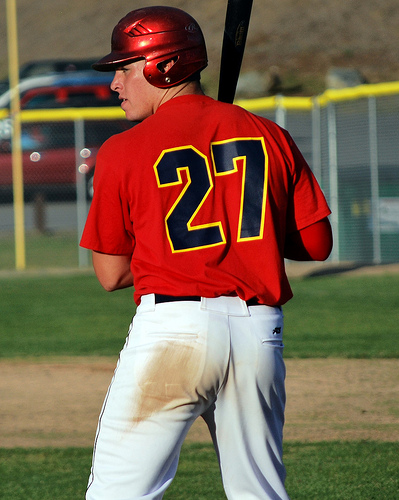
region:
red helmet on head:
[97, 6, 204, 89]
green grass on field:
[289, 444, 397, 498]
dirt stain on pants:
[127, 333, 212, 423]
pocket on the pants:
[149, 328, 204, 352]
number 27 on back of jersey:
[152, 136, 275, 249]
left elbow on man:
[95, 266, 126, 299]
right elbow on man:
[295, 234, 346, 265]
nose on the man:
[108, 74, 120, 86]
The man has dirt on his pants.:
[123, 346, 214, 429]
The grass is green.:
[307, 446, 391, 495]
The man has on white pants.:
[84, 298, 298, 496]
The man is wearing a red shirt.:
[80, 92, 337, 300]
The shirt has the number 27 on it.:
[129, 132, 289, 271]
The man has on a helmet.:
[91, 0, 207, 80]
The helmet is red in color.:
[82, 1, 213, 89]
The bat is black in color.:
[215, 0, 248, 98]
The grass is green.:
[22, 287, 92, 330]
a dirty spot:
[126, 333, 237, 429]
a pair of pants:
[81, 293, 296, 499]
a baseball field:
[3, 230, 396, 499]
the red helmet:
[98, 9, 214, 87]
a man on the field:
[76, 8, 331, 497]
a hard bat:
[215, 3, 255, 102]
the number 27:
[150, 131, 273, 256]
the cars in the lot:
[0, 49, 147, 204]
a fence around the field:
[2, 80, 398, 269]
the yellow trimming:
[0, 79, 397, 124]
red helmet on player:
[84, 5, 207, 85]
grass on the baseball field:
[297, 282, 398, 354]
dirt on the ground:
[2, 358, 99, 446]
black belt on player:
[150, 291, 264, 309]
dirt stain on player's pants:
[130, 342, 202, 417]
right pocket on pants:
[257, 336, 287, 351]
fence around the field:
[332, 102, 395, 269]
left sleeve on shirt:
[71, 132, 131, 258]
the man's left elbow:
[89, 266, 123, 295]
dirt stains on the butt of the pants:
[123, 338, 218, 436]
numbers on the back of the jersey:
[148, 134, 283, 268]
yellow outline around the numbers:
[142, 132, 280, 256]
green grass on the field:
[0, 443, 398, 496]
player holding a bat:
[56, 1, 348, 498]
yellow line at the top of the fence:
[0, 82, 397, 127]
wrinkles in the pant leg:
[245, 370, 303, 499]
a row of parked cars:
[0, 46, 182, 220]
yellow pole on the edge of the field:
[5, 1, 35, 272]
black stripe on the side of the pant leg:
[82, 310, 135, 498]